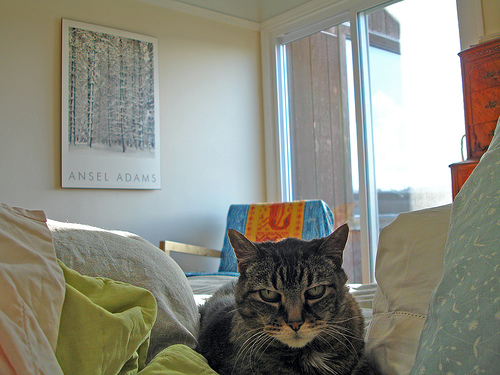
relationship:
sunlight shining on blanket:
[49, 205, 149, 248] [62, 210, 171, 283]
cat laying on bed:
[196, 221, 374, 375] [170, 272, 375, 353]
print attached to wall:
[52, 40, 160, 192] [8, 38, 261, 272]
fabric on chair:
[217, 197, 334, 279] [157, 200, 333, 287]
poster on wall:
[60, 19, 161, 189] [185, 104, 249, 192]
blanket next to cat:
[56, 258, 215, 374] [215, 217, 375, 373]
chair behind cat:
[233, 190, 296, 228] [229, 269, 351, 352]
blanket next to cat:
[456, 254, 494, 346] [189, 223, 381, 366]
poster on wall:
[41, 19, 171, 196] [163, 89, 248, 207]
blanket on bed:
[61, 272, 171, 368] [13, 222, 153, 352]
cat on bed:
[230, 246, 339, 356] [95, 258, 187, 365]